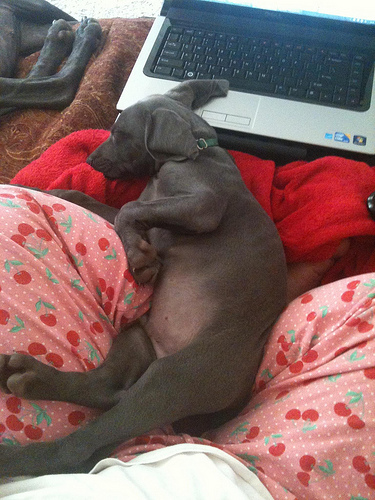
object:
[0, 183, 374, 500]
fabric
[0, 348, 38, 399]
foot of dog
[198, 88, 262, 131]
touchpad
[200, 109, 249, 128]
mouse buttons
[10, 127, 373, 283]
towel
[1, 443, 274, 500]
sheet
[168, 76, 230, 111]
ear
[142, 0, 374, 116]
keboard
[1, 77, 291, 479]
dog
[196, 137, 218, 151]
colar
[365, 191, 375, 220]
mouse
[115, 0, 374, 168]
laptop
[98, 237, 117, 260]
cherry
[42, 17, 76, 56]
dog's feet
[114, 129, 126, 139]
dog's eyes